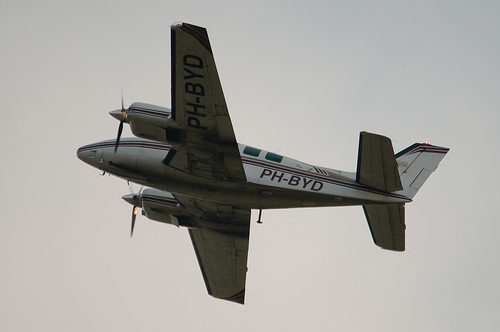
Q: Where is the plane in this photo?
A: In the sky.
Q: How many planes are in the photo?
A: One.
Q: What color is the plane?
A: White.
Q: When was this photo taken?
A: In the daytime.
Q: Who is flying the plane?
A: A pilot.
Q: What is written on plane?
A: PH-BYD.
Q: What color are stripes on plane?
A: Red.